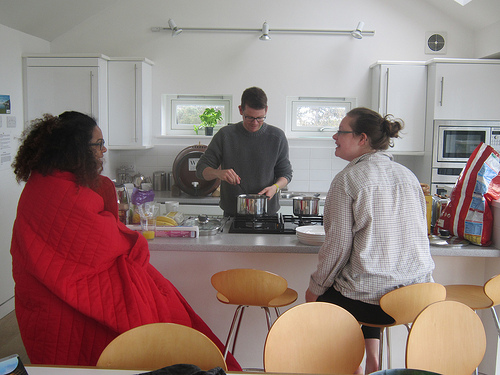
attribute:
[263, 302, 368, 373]
stool — brown 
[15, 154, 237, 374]
blanket — red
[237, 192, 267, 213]
pot — silver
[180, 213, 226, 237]
pot lid — silver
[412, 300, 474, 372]
stool — light brown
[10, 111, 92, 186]
hair — brown, curly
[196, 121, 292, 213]
shirt — long sleeved, grey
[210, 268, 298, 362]
stool — light brown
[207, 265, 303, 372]
stool — light brown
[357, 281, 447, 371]
stool — light brown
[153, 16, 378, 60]
lights — three 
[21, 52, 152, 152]
cabinet — white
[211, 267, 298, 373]
stool — light brown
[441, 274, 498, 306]
stool — light brown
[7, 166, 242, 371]
blanket — red, quilted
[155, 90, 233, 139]
window — white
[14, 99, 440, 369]
women — seated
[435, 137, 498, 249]
snack bag — large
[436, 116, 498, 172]
microwave — silver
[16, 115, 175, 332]
woman — red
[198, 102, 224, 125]
plant — potted, green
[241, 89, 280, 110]
hair — brown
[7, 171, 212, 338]
blanket — large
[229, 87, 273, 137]
head — man's